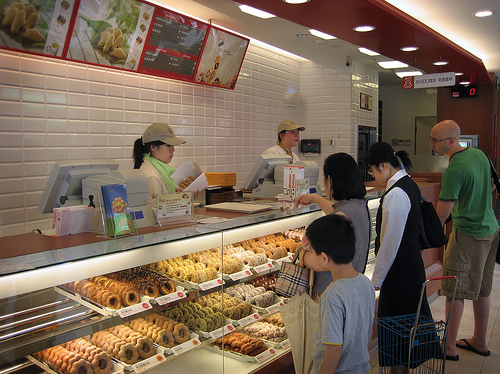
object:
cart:
[377, 275, 460, 373]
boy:
[304, 213, 376, 374]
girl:
[262, 120, 306, 164]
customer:
[430, 120, 500, 361]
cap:
[143, 123, 188, 145]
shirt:
[310, 272, 376, 374]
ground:
[369, 261, 500, 373]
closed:
[275, 255, 341, 370]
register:
[251, 156, 322, 202]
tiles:
[0, 0, 380, 236]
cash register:
[39, 157, 156, 231]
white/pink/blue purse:
[275, 245, 315, 298]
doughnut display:
[1, 211, 380, 374]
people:
[293, 152, 371, 297]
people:
[359, 142, 440, 372]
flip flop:
[436, 345, 462, 363]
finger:
[295, 198, 300, 208]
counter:
[0, 172, 454, 372]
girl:
[133, 123, 200, 209]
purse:
[395, 186, 451, 249]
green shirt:
[439, 148, 500, 237]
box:
[170, 162, 209, 193]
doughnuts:
[175, 178, 193, 192]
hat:
[276, 120, 305, 131]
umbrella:
[277, 243, 321, 373]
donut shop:
[2, 0, 500, 374]